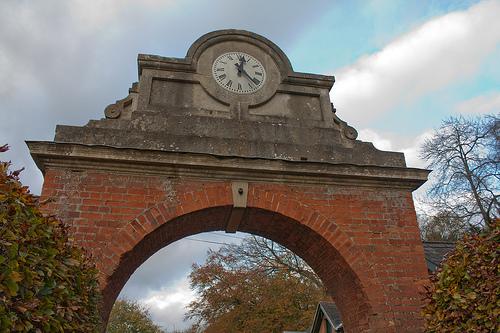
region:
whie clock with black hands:
[185, 30, 286, 139]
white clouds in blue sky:
[13, 8, 55, 58]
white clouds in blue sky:
[16, 43, 39, 65]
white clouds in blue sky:
[62, 36, 133, 113]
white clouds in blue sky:
[291, 16, 324, 39]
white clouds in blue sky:
[366, 13, 400, 49]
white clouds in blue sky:
[388, 32, 449, 100]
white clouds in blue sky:
[89, 28, 139, 80]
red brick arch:
[86, 165, 390, 282]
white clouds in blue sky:
[378, 24, 416, 73]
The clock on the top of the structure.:
[215, 46, 268, 91]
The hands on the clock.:
[235, 53, 256, 87]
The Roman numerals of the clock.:
[215, 50, 263, 94]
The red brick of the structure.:
[44, 168, 421, 332]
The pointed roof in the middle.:
[312, 300, 341, 332]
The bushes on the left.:
[2, 148, 109, 331]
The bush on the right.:
[417, 233, 499, 331]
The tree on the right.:
[412, 108, 499, 235]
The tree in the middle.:
[200, 239, 342, 331]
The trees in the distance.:
[118, 298, 188, 331]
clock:
[197, 28, 273, 113]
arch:
[131, 202, 324, 330]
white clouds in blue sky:
[42, 28, 73, 69]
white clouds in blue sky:
[404, 21, 443, 59]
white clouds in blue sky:
[369, 60, 437, 115]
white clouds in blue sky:
[161, 248, 194, 289]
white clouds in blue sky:
[339, 25, 392, 63]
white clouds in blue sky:
[39, 33, 62, 58]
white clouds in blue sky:
[7, 65, 51, 95]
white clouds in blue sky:
[72, 21, 102, 65]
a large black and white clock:
[212, 51, 265, 93]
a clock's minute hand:
[236, 66, 254, 82]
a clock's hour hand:
[237, 53, 244, 71]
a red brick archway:
[33, 185, 426, 330]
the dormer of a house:
[308, 301, 345, 330]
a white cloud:
[335, 12, 482, 113]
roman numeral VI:
[235, 81, 242, 91]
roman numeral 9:
[211, 66, 226, 72]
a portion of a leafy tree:
[185, 260, 305, 326]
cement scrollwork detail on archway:
[102, 81, 135, 118]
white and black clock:
[209, 41, 268, 96]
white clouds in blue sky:
[17, 39, 53, 96]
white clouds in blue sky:
[408, 34, 428, 79]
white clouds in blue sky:
[355, 51, 397, 104]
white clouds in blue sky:
[153, 268, 179, 297]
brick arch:
[85, 174, 412, 279]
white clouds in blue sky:
[36, 3, 80, 74]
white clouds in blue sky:
[287, 26, 339, 46]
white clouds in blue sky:
[433, 17, 486, 92]